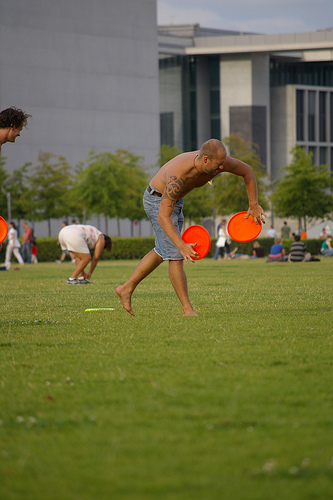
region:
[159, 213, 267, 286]
holding two frisbees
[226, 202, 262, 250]
the frisbee is orange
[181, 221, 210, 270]
the frisbee is red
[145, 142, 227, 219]
he has no shirt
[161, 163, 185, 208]
he has a tattoo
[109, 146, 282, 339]
standing in a grassy field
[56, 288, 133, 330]
the frisbee is green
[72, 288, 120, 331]
frisbee on the ground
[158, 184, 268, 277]
trying to throw frisbees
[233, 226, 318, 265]
people are sitting down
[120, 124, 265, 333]
this is a man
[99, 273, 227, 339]
the man is barefoot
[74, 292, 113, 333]
a green frisbee in the grass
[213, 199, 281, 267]
this is a frisbee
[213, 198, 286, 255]
the frisbee is orange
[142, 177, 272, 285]
man holding two frisbees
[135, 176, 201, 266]
man wearing blue jean shorts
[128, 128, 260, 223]
man without a shirt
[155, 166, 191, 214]
man has a tattoo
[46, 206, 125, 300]
person is bending over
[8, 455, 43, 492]
Small patch of green grass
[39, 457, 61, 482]
Small patch of green grass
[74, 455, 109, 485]
Small patch of green grass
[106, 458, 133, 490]
Small patch of green grass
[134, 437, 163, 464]
Small patch of green grass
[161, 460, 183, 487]
Small patch of green grass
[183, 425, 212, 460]
Small patch of green grass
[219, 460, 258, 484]
Small patch of green grass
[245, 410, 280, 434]
Small patch of green grass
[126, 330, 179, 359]
Small patch of green grass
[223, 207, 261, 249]
Orange frisbee in hand.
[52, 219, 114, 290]
Woman bending over.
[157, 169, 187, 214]
Tattoo on the arm.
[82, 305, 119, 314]
yellow frisbee on the ground.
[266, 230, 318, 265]
People sitting in the grass.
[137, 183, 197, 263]
blue jean shorts on the man.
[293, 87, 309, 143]
Window in the building.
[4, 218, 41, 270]
People walking in the background.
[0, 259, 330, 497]
Green grass covering the surface.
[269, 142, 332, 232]
Tree in the background.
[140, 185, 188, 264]
Man wearing shorts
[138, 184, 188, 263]
Man is wearing shorts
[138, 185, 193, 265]
Man wearing blue shorts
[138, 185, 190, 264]
Man is wearing blue shorts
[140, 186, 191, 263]
Man wearing jean shorts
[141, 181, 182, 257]
Man is wearing jeans shorts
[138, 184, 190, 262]
Man wearing blue jeans shorts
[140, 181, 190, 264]
Man is wearing blue jean shorts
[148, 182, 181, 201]
Man wearing a black belt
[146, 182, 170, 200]
Man is wearing a black belt